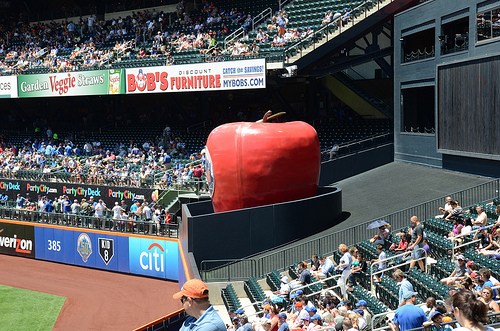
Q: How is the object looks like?
A: Red.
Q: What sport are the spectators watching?
A: Baseball.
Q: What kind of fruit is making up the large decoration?
A: An apple.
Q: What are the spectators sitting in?
A: The stands.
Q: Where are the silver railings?
A: In the stands.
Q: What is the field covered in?
A: Grass.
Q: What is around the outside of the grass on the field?
A: Dirt.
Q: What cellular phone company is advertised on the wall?
A: Verizon.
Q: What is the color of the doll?
A: Red.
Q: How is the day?
A: Sunny.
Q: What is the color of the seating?
A: Black.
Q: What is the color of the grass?
A: Green.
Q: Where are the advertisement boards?
A: In the side banner.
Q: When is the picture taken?
A: Daytime.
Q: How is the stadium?
A: Almost full.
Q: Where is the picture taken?
A: At a baseball stadium.